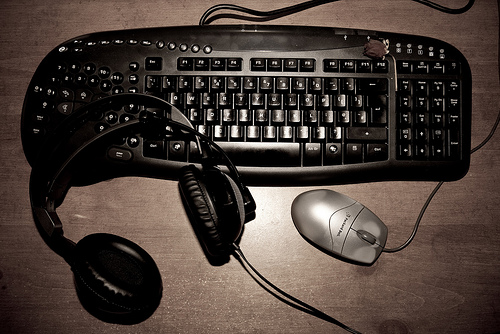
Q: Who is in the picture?
A: No one.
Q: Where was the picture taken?
A: Computer desk.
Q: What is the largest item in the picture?
A: Keyboard.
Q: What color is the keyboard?
A: Black.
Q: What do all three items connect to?
A: Computer.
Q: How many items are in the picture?
A: Three.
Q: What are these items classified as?
A: Computer peripherals.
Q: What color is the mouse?
A: Silver.